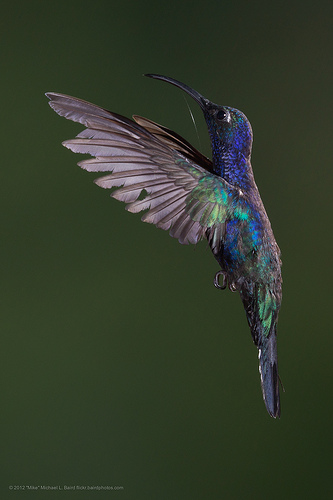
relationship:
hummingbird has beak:
[45, 73, 286, 420] [143, 72, 204, 113]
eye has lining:
[215, 110, 227, 122] [214, 107, 232, 125]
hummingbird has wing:
[45, 73, 286, 420] [45, 90, 229, 251]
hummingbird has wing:
[45, 73, 286, 420] [130, 116, 217, 183]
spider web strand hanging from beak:
[178, 86, 208, 172] [143, 72, 204, 113]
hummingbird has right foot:
[45, 73, 286, 420] [228, 279, 238, 292]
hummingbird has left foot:
[45, 73, 286, 420] [213, 270, 229, 288]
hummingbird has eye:
[45, 73, 286, 420] [215, 110, 227, 122]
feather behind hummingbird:
[214, 187, 226, 207] [45, 73, 286, 420]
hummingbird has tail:
[45, 73, 286, 420] [244, 297, 282, 418]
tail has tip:
[244, 297, 282, 418] [256, 356, 284, 417]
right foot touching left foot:
[228, 279, 238, 292] [213, 270, 229, 288]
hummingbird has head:
[45, 73, 286, 420] [204, 104, 252, 163]